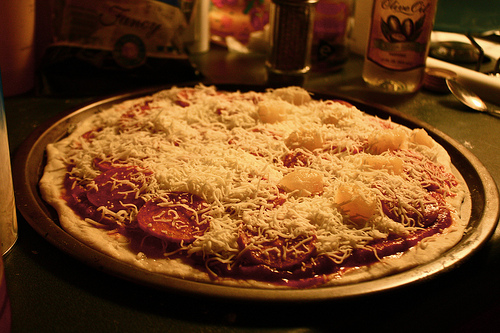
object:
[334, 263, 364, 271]
cheese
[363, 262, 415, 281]
pan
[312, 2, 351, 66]
bottle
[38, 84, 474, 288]
frozen pizza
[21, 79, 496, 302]
tray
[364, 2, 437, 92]
bottle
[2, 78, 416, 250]
table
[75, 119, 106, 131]
pan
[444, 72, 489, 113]
spoon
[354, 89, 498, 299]
platter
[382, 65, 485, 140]
table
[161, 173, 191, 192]
cheese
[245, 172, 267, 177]
cheese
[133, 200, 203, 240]
pepperoni